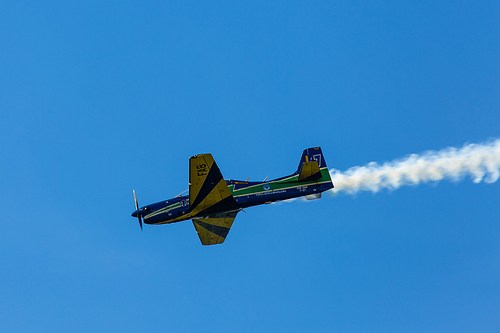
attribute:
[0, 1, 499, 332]
sky — blue, clear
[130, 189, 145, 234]
propeller — spinning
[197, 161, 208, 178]
letters — black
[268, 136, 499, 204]
smoke trail — white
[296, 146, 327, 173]
tail fin — mostly blue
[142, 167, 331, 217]
stripe — green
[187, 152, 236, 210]
wing — blue, yellow, large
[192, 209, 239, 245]
wing — blue, yellow, large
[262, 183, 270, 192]
circle — blue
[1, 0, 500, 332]
day — clear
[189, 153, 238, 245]
wing span — large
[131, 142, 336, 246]
airplane — flying, blue, yellow, colorful, multi colored, small, mid air